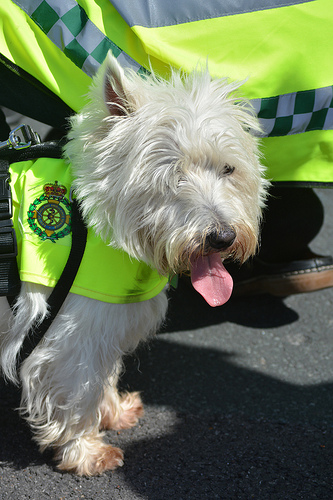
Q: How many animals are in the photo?
A: One.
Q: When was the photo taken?
A: During the day.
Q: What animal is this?
A: Dog.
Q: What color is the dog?
A: White.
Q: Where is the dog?
A: On the street.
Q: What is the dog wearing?
A: A yellow vest.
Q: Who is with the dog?
A: A person.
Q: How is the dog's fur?
A: Shaggy.